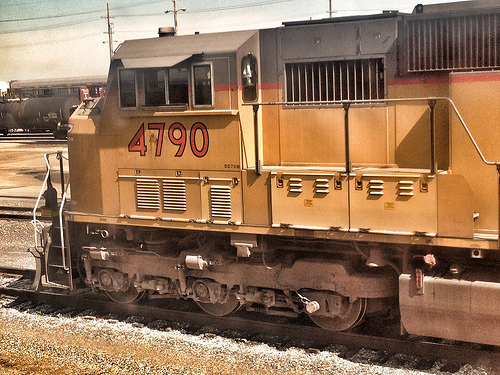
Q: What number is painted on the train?
A: 4790.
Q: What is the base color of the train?
A: Orange.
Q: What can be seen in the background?
A: Powerlines.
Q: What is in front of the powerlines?
A: A train.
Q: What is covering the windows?
A: Railings.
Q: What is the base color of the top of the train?
A: Black.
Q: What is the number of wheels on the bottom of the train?
A: Three.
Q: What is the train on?
A: Tracks.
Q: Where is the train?
A: On the tracks.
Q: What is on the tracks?
A: A yellow locomotive.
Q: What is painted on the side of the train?
A: Numbers.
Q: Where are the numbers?
A: On the side of the train.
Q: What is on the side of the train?
A: Windows.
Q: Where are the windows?
A: On the locomotive.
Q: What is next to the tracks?
A: Gravel.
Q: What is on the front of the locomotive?
A: A stairway.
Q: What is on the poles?
A: Wires.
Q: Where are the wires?
A: On the poles.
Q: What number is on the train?
A: 4790.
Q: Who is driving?
A: The conductor.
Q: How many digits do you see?
A: 4.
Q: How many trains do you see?
A: 2.